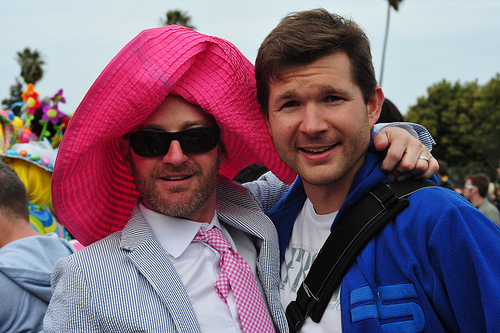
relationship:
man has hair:
[254, 7, 496, 332] [252, 9, 375, 116]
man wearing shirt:
[36, 24, 444, 333] [150, 212, 277, 332]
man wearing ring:
[36, 24, 444, 333] [381, 139, 440, 176]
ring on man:
[414, 151, 434, 166] [76, 47, 295, 331]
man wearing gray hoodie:
[2, 163, 79, 331] [0, 235, 77, 330]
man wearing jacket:
[36, 24, 444, 333] [33, 194, 301, 329]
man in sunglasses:
[40, 89, 440, 331] [118, 120, 221, 160]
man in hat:
[40, 89, 440, 331] [44, 19, 301, 246]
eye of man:
[319, 88, 348, 106] [254, 7, 496, 332]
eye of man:
[275, 98, 301, 112] [55, 51, 296, 330]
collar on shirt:
[136, 210, 237, 260] [137, 201, 255, 331]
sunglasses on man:
[119, 124, 304, 205] [44, 43, 308, 323]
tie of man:
[196, 226, 288, 331] [41, 13, 306, 328]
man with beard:
[41, 13, 306, 328] [148, 173, 209, 217]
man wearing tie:
[41, 13, 306, 328] [192, 220, 268, 330]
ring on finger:
[418, 156, 429, 162] [352, 135, 449, 185]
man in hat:
[41, 13, 306, 328] [39, 41, 265, 208]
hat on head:
[44, 19, 301, 246] [115, 95, 222, 221]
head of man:
[115, 95, 222, 221] [41, 13, 306, 328]